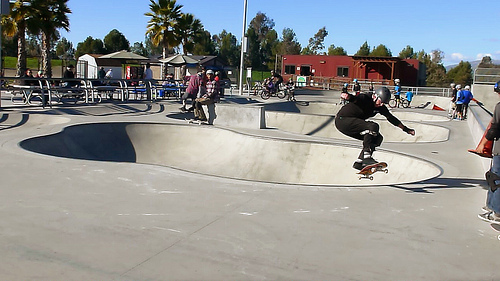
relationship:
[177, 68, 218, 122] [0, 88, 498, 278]
people on pavement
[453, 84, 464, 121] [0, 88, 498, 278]
boy on pavement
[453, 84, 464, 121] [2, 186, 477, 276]
boy on pavement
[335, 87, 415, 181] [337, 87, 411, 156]
boy wearing clothes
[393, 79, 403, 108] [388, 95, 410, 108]
kid on bicycle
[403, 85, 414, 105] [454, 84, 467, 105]
boy wearing top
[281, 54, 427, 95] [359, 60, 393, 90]
building with porch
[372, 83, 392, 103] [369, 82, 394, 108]
helmet on head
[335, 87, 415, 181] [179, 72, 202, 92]
boy with shirt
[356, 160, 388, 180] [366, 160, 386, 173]
skateboard with bottom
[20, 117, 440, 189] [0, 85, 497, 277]
ramp in skate park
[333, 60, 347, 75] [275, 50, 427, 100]
window on building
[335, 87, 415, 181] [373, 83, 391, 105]
boy wearing head gear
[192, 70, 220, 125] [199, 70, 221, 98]
people wearing shirt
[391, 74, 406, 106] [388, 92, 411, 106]
kid on bicycle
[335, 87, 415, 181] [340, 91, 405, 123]
boy wearing black shirt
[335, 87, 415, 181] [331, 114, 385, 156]
boy wearing jeans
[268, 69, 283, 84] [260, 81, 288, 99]
guy riding bicycle